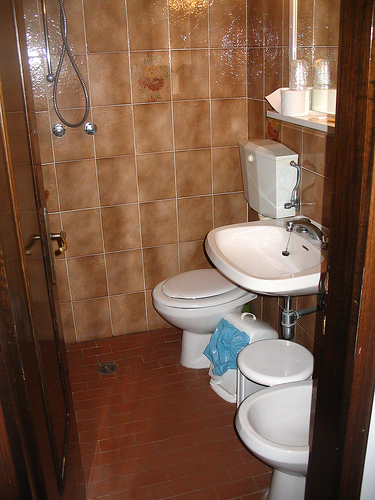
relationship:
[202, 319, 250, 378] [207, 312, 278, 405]
plastic bag in trash can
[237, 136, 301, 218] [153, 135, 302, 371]
cistern of toilet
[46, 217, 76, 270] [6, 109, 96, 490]
handle of door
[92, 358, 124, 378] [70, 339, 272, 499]
drain in floor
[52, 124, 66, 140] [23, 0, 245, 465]
knob on shower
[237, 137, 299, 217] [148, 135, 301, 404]
flushing system on toilet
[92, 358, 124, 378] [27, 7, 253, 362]
drain in shower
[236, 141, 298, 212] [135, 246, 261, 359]
tank on toilet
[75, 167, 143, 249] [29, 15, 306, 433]
tiles on wall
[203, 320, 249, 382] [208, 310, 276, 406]
bag in garbage can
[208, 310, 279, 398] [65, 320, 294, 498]
garbage can sitting on floor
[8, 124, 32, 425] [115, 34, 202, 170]
door on side of wall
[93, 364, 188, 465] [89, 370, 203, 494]
brick tiles covering floor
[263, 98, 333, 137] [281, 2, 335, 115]
shelf under mirror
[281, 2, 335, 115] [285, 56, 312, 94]
mirror holding plastic cups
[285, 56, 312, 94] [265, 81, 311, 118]
cups and toilet paper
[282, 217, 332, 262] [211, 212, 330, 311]
faucet on wash basin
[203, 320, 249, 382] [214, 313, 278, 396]
bag on trash can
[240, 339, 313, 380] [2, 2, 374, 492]
equipment used in bathroom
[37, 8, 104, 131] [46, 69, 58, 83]
shower hose with shower head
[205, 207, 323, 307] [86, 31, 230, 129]
sink attached to wall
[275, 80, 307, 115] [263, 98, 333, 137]
toilet paper on shelf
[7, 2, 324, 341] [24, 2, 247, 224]
bathroom walls covered with tiles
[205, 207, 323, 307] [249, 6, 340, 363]
sink attached to wall